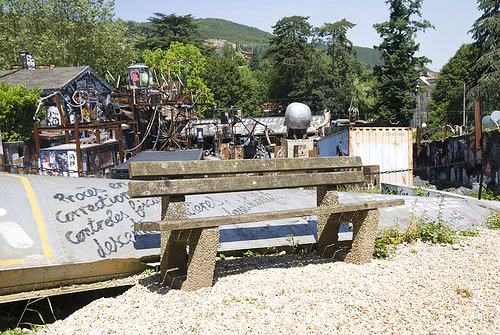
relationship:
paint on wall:
[350, 142, 405, 165] [350, 125, 418, 182]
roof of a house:
[200, 117, 281, 134] [208, 132, 298, 161]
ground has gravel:
[162, 269, 497, 323] [292, 278, 298, 283]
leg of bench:
[155, 229, 220, 290] [128, 162, 412, 290]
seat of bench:
[133, 192, 409, 230] [122, 153, 411, 295]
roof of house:
[7, 58, 104, 93] [1, 48, 143, 180]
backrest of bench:
[127, 155, 364, 215] [122, 153, 411, 295]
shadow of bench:
[144, 224, 384, 304] [122, 153, 411, 295]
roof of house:
[173, 117, 280, 136] [181, 110, 329, 152]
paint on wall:
[0, 172, 499, 270] [25, 178, 160, 284]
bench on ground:
[93, 147, 385, 259] [3, 227, 484, 333]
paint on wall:
[0, 172, 499, 270] [19, 206, 107, 239]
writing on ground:
[51, 180, 159, 255] [1, 167, 352, 267]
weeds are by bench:
[370, 199, 499, 252] [128, 162, 412, 290]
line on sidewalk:
[10, 168, 74, 284] [3, 167, 172, 273]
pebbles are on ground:
[42, 234, 494, 334] [55, 248, 499, 332]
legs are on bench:
[159, 220, 382, 290] [128, 162, 412, 290]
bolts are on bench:
[161, 172, 172, 188] [115, 150, 419, 270]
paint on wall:
[0, 172, 499, 270] [0, 171, 500, 269]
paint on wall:
[0, 172, 499, 270] [10, 177, 498, 255]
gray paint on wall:
[35, 177, 50, 198] [4, 168, 373, 278]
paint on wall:
[0, 172, 499, 270] [2, 162, 356, 281]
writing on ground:
[51, 180, 159, 255] [218, 250, 398, 333]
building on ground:
[171, 107, 343, 165] [362, 101, 412, 129]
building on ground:
[0, 50, 149, 173] [362, 101, 412, 129]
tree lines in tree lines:
[8, 2, 269, 121] [269, 0, 429, 124]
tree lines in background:
[8, 2, 269, 121] [4, 2, 483, 82]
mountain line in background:
[184, 17, 267, 44] [5, 8, 432, 81]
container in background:
[315, 124, 414, 189] [17, 22, 499, 326]